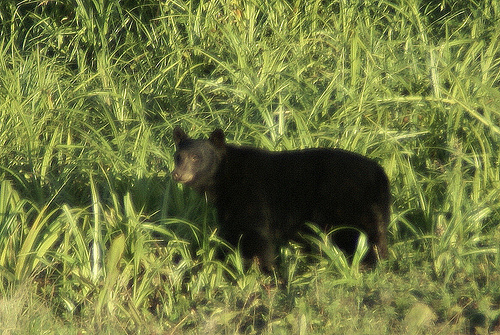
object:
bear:
[169, 125, 395, 275]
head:
[172, 126, 227, 184]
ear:
[208, 128, 226, 143]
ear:
[170, 126, 188, 141]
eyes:
[174, 155, 180, 162]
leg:
[252, 235, 284, 277]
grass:
[1, 2, 499, 334]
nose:
[173, 170, 184, 181]